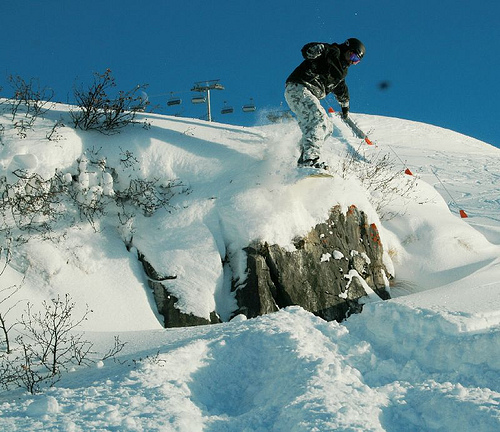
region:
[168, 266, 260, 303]
Snow covering the ground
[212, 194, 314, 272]
Snow covering the ground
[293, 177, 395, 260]
Snow covering the ground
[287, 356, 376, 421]
Snow covering the ground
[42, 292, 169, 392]
Snow covering the ground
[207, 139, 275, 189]
Snow covering the ground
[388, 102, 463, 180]
Snow covering the ground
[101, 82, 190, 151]
Snow covering the ground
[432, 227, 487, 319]
Snow covering the ground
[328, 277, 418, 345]
Snow covering the ground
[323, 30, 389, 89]
man is wearing a helmet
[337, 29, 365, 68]
man is wearing a helmet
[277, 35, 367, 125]
the jacket is black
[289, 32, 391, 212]
the jacket is black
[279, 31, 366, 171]
snowboarder going down the slope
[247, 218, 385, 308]
rock wall on the slope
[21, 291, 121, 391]
bushes sticking out of the snow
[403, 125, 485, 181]
ski trails on the white snow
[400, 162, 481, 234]
orange flags bordering the slope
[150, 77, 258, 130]
ski lift at the top of the slope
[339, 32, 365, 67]
black helmet and goggles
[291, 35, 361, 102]
black ski jacket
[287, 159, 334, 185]
white snow board in the snow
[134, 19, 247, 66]
clear bright blue sky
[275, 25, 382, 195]
a person on a snowboard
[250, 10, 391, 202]
a snowboarder on a rock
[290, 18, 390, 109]
a person wearing a black jacket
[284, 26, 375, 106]
a black winter jacket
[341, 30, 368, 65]
a person wearing a black helmet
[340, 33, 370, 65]
a person wearing goggles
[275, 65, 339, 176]
a person wearing snowpants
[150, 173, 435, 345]
a snow covered rock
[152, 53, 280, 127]
a ski lift in the distance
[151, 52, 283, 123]
a chair lift in the distance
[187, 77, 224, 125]
Metal ski lift pole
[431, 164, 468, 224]
Orange warning flag indicator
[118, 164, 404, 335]
Rock outcropping on slope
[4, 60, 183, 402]
Snow covered shrubs on mountain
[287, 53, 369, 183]
Snowboarder jumping off of rock face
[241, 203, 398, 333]
Bare rock face of outcropping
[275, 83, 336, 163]
Snow covered pants of man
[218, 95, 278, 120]
Empty ski lift chairs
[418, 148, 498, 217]
ski tracks in the snow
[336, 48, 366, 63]
Goggles on snowboarder's face